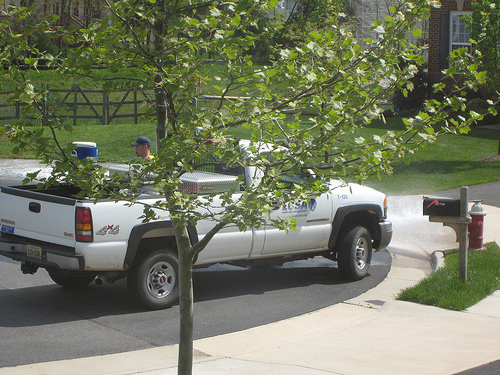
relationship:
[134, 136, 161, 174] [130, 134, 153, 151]
man in cap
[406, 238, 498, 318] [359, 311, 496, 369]
patch on sidewalk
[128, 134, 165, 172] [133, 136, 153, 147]
man in cap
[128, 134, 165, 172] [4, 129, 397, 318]
man by truck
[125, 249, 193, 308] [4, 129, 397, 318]
tire on truck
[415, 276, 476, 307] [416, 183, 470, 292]
grass growing by mailbox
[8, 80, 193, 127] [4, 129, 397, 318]
fence behind truck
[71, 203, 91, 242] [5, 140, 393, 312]
light on truck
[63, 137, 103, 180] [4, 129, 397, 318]
cooler on truck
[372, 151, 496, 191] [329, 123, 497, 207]
shadows on lawn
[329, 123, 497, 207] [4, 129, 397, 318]
lawn to right of truck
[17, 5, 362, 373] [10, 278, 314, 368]
tree by a road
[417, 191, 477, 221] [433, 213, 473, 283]
mailbox on a post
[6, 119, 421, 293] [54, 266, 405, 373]
truck on a road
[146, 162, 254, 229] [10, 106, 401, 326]
box in a truck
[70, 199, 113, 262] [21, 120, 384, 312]
light on truck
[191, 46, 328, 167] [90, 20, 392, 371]
leaves on a tree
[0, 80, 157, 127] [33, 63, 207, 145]
fence in a yard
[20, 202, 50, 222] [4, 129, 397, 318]
handle on truck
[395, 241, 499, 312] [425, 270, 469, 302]
patch of grass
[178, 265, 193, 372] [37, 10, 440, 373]
trunk of a tree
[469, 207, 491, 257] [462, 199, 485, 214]
fire hydrant with a top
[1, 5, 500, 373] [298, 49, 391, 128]
tree with leaves